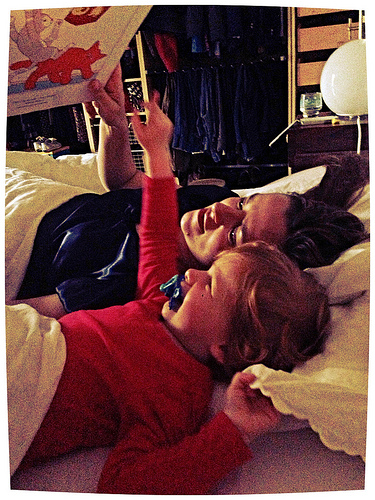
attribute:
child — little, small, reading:
[7, 87, 331, 492]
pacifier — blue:
[161, 274, 182, 310]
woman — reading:
[8, 61, 370, 320]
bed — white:
[9, 164, 367, 493]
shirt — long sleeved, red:
[20, 173, 253, 494]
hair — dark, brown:
[279, 147, 374, 271]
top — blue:
[12, 182, 244, 316]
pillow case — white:
[240, 290, 374, 466]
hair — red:
[205, 238, 329, 384]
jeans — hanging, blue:
[197, 65, 215, 153]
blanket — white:
[4, 147, 112, 476]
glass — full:
[297, 92, 325, 117]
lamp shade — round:
[319, 36, 368, 119]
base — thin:
[354, 114, 362, 156]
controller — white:
[269, 114, 335, 147]